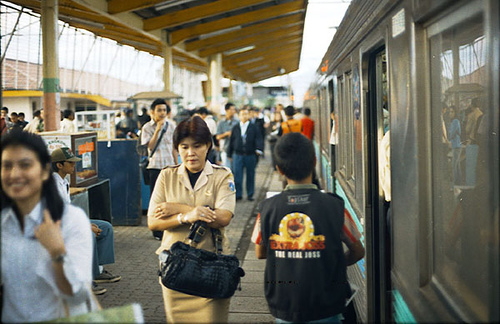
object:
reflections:
[438, 97, 492, 186]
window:
[431, 14, 487, 324]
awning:
[11, 2, 303, 80]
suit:
[144, 165, 235, 322]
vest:
[256, 187, 346, 323]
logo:
[268, 211, 325, 259]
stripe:
[40, 77, 62, 92]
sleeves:
[343, 211, 362, 246]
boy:
[46, 146, 120, 296]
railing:
[75, 114, 124, 145]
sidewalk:
[225, 158, 285, 323]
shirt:
[147, 159, 236, 254]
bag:
[161, 210, 246, 299]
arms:
[140, 187, 187, 227]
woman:
[0, 129, 95, 324]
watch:
[176, 212, 182, 224]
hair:
[173, 119, 212, 149]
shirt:
[281, 120, 300, 133]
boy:
[251, 132, 364, 323]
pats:
[230, 152, 260, 201]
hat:
[50, 146, 82, 163]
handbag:
[140, 122, 171, 185]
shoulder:
[145, 120, 178, 128]